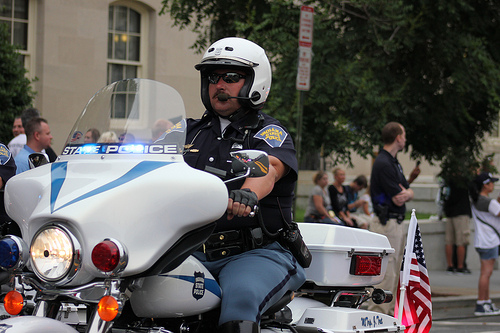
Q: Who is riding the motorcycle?
A: A policeman.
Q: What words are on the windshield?
A: State Police.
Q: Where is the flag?
A: On the back of the motorcycle.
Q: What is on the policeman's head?
A: Helmet.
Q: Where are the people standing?
A: On the curb.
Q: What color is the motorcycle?
A: White and blue.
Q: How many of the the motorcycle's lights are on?
A: One.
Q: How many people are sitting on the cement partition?
A: Three.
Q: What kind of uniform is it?
A: Police.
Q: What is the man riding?
A: A bike.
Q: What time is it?
A: Afternoon.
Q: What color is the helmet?
A: White.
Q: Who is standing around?
A: Some people.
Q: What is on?
A: The headlight of the motorcycle.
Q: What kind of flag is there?
A: American.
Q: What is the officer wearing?
A: Glasses.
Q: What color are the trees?
A: Green.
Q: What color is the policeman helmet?
A: White.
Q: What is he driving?
A: A motorcycle.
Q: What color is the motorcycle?
A: White and Blue.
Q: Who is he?
A: A policeman.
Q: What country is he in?
A: USA.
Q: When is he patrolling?
A: During daylight.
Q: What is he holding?
A: Handlebars.